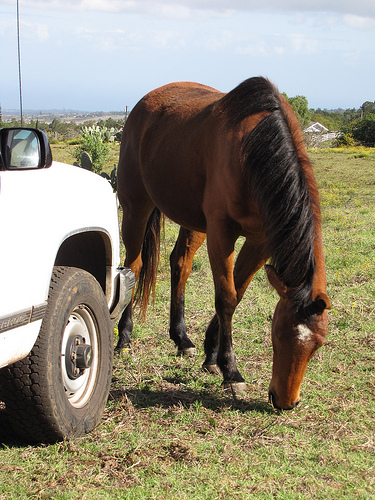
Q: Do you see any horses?
A: Yes, there is a horse.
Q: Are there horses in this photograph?
A: Yes, there is a horse.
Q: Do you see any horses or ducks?
A: Yes, there is a horse.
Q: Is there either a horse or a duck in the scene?
A: Yes, there is a horse.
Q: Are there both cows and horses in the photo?
A: No, there is a horse but no cows.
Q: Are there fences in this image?
A: No, there are no fences.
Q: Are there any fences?
A: No, there are no fences.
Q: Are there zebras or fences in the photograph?
A: No, there are no fences or zebras.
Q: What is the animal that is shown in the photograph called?
A: The animal is a horse.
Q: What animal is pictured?
A: The animal is a horse.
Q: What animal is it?
A: The animal is a horse.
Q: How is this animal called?
A: That is a horse.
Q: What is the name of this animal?
A: That is a horse.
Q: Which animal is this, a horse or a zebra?
A: That is a horse.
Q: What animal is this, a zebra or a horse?
A: That is a horse.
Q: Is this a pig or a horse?
A: This is a horse.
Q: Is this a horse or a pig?
A: This is a horse.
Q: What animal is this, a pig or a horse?
A: This is a horse.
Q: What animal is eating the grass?
A: The horse is eating the grass.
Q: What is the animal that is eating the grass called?
A: The animal is a horse.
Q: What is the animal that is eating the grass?
A: The animal is a horse.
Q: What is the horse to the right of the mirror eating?
A: The horse is eating grass.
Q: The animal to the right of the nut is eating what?
A: The horse is eating grass.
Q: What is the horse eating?
A: The horse is eating grass.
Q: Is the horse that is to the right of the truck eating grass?
A: Yes, the horse is eating grass.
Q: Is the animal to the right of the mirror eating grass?
A: Yes, the horse is eating grass.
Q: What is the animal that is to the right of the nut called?
A: The animal is a horse.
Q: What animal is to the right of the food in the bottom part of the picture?
A: The animal is a horse.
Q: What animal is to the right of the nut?
A: The animal is a horse.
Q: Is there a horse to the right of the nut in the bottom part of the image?
A: Yes, there is a horse to the right of the nut.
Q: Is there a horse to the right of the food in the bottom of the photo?
A: Yes, there is a horse to the right of the nut.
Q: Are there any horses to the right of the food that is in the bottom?
A: Yes, there is a horse to the right of the nut.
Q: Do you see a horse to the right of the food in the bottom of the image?
A: Yes, there is a horse to the right of the nut.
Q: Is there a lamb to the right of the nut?
A: No, there is a horse to the right of the nut.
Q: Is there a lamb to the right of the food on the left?
A: No, there is a horse to the right of the nut.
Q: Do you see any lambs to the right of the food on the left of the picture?
A: No, there is a horse to the right of the nut.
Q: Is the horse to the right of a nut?
A: Yes, the horse is to the right of a nut.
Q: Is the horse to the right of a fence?
A: No, the horse is to the right of a nut.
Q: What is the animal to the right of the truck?
A: The animal is a horse.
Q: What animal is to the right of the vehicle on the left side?
A: The animal is a horse.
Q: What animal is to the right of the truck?
A: The animal is a horse.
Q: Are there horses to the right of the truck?
A: Yes, there is a horse to the right of the truck.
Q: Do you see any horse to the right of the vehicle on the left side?
A: Yes, there is a horse to the right of the truck.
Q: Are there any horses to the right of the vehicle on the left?
A: Yes, there is a horse to the right of the truck.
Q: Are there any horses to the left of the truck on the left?
A: No, the horse is to the right of the truck.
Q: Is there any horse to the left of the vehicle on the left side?
A: No, the horse is to the right of the truck.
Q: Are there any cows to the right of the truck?
A: No, there is a horse to the right of the truck.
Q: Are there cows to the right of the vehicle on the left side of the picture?
A: No, there is a horse to the right of the truck.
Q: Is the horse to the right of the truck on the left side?
A: Yes, the horse is to the right of the truck.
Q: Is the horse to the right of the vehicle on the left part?
A: Yes, the horse is to the right of the truck.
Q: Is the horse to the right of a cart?
A: No, the horse is to the right of the truck.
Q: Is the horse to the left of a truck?
A: No, the horse is to the right of a truck.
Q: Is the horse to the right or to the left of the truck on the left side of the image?
A: The horse is to the right of the truck.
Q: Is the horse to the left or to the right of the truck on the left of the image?
A: The horse is to the right of the truck.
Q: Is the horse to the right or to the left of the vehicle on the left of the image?
A: The horse is to the right of the truck.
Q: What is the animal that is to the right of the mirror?
A: The animal is a horse.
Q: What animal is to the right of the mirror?
A: The animal is a horse.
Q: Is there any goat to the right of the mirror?
A: No, there is a horse to the right of the mirror.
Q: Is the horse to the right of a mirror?
A: Yes, the horse is to the right of a mirror.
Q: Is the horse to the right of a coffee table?
A: No, the horse is to the right of a mirror.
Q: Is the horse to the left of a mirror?
A: No, the horse is to the right of a mirror.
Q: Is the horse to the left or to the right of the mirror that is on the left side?
A: The horse is to the right of the mirror.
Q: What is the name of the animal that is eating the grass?
A: The animal is a horse.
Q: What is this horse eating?
A: The horse is eating grass.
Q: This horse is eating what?
A: The horse is eating grass.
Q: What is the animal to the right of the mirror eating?
A: The horse is eating grass.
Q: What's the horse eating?
A: The horse is eating grass.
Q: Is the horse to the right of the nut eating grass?
A: Yes, the horse is eating grass.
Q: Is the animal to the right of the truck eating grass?
A: Yes, the horse is eating grass.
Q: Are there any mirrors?
A: Yes, there is a mirror.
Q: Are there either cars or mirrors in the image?
A: Yes, there is a mirror.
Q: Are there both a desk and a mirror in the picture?
A: No, there is a mirror but no desks.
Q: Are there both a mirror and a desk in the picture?
A: No, there is a mirror but no desks.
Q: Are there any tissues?
A: No, there are no tissues.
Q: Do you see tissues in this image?
A: No, there are no tissues.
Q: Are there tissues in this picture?
A: No, there are no tissues.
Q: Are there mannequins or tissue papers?
A: No, there are no tissue papers or mannequins.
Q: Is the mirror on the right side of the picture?
A: No, the mirror is on the left of the image.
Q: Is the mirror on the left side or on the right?
A: The mirror is on the left of the image.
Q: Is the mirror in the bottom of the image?
A: No, the mirror is in the top of the image.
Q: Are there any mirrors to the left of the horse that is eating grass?
A: Yes, there is a mirror to the left of the horse.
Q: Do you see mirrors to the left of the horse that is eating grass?
A: Yes, there is a mirror to the left of the horse.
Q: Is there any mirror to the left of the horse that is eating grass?
A: Yes, there is a mirror to the left of the horse.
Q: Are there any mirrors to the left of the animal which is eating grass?
A: Yes, there is a mirror to the left of the horse.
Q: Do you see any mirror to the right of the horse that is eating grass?
A: No, the mirror is to the left of the horse.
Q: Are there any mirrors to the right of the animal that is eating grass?
A: No, the mirror is to the left of the horse.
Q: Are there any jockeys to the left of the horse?
A: No, there is a mirror to the left of the horse.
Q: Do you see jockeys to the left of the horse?
A: No, there is a mirror to the left of the horse.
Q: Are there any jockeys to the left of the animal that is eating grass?
A: No, there is a mirror to the left of the horse.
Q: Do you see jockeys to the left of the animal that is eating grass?
A: No, there is a mirror to the left of the horse.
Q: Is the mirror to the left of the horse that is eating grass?
A: Yes, the mirror is to the left of the horse.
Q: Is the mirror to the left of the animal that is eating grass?
A: Yes, the mirror is to the left of the horse.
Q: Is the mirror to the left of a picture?
A: No, the mirror is to the left of the horse.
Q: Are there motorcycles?
A: No, there are no motorcycles.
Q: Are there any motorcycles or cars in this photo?
A: No, there are no motorcycles or cars.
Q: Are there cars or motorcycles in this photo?
A: No, there are no motorcycles or cars.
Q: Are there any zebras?
A: No, there are no zebras.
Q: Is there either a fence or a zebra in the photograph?
A: No, there are no zebras or fences.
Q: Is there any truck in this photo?
A: Yes, there is a truck.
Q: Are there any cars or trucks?
A: Yes, there is a truck.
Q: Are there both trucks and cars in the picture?
A: No, there is a truck but no cars.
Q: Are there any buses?
A: No, there are no buses.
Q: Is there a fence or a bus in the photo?
A: No, there are no buses or fences.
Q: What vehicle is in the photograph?
A: The vehicle is a truck.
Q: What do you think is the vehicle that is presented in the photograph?
A: The vehicle is a truck.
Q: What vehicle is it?
A: The vehicle is a truck.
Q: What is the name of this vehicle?
A: This is a truck.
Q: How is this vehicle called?
A: This is a truck.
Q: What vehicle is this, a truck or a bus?
A: This is a truck.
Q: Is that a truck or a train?
A: That is a truck.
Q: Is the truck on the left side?
A: Yes, the truck is on the left of the image.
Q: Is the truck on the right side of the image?
A: No, the truck is on the left of the image.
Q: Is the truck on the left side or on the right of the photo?
A: The truck is on the left of the image.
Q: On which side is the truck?
A: The truck is on the left of the image.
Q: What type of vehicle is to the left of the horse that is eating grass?
A: The vehicle is a truck.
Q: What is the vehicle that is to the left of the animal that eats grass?
A: The vehicle is a truck.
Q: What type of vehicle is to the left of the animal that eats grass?
A: The vehicle is a truck.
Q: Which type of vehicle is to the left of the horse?
A: The vehicle is a truck.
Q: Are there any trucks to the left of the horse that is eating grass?
A: Yes, there is a truck to the left of the horse.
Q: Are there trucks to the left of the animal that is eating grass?
A: Yes, there is a truck to the left of the horse.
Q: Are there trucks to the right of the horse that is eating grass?
A: No, the truck is to the left of the horse.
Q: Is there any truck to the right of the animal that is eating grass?
A: No, the truck is to the left of the horse.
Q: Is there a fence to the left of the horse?
A: No, there is a truck to the left of the horse.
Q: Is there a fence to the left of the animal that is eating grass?
A: No, there is a truck to the left of the horse.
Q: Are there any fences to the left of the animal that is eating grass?
A: No, there is a truck to the left of the horse.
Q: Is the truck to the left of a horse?
A: Yes, the truck is to the left of a horse.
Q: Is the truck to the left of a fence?
A: No, the truck is to the left of a horse.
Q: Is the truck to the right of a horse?
A: No, the truck is to the left of a horse.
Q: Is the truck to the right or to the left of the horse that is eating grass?
A: The truck is to the left of the horse.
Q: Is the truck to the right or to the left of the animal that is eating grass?
A: The truck is to the left of the horse.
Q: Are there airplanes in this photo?
A: No, there are no airplanes.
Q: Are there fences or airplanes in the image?
A: No, there are no airplanes or fences.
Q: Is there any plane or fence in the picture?
A: No, there are no airplanes or fences.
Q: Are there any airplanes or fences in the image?
A: No, there are no airplanes or fences.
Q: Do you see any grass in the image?
A: Yes, there is grass.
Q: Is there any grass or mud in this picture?
A: Yes, there is grass.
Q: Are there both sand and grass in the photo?
A: No, there is grass but no sand.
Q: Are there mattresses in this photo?
A: No, there are no mattresses.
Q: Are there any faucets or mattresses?
A: No, there are no mattresses or faucets.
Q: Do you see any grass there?
A: Yes, there is grass.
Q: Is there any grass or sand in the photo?
A: Yes, there is grass.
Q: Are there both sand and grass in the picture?
A: No, there is grass but no sand.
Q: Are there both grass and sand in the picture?
A: No, there is grass but no sand.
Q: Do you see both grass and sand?
A: No, there is grass but no sand.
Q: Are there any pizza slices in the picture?
A: No, there are no pizza slices.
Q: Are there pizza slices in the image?
A: No, there are no pizza slices.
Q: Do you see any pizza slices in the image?
A: No, there are no pizza slices.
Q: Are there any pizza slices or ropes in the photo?
A: No, there are no pizza slices or ropes.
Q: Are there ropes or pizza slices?
A: No, there are no pizza slices or ropes.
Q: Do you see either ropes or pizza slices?
A: No, there are no pizza slices or ropes.